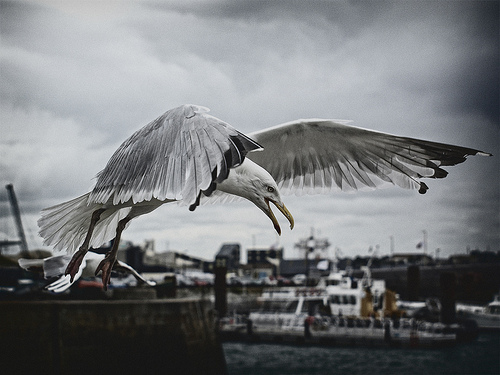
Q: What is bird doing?
A: Flying.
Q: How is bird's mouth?
A: Open.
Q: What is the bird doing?
A: Flying.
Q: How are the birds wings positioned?
A: Outstretched.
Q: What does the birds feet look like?
A: Webbed.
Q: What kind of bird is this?
A: Seagull.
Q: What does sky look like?
A: Cloudy.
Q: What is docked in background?
A: Boat.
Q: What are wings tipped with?
A: Black.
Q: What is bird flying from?
A: Buoy.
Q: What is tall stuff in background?
A: Lights.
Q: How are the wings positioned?
A: Spread open.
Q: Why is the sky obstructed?
A: Cloud cover.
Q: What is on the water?
A: Boats.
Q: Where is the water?
A: Right foreground.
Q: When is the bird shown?
A: Cloudy day.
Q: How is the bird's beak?
A: Open.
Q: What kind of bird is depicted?
A: Seagull.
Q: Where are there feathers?
A: Bird's body.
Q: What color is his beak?
A: Yellow.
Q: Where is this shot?
A: Dock.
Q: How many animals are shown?
A: 1.